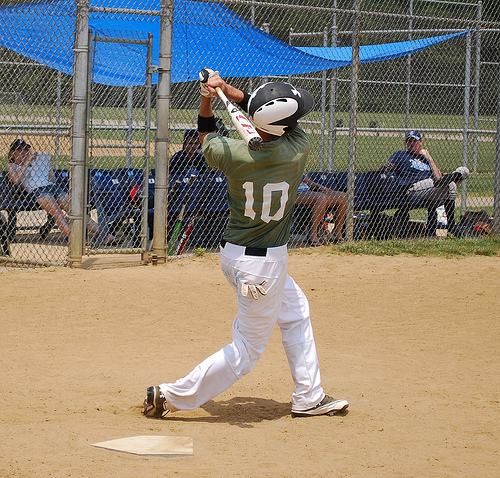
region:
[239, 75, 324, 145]
white and black helmet on baseball player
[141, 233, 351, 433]
white pants on baseball player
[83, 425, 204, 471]
white home plate next to baseball player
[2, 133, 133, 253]
person behind fence watching baseball player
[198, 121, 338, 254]
baseball player with green shirt and white numbers on it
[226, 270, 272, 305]
white glove in back pocket of baseball player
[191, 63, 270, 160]
baseball bat in the hands of baseball player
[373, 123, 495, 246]
man in blue uniform behind fence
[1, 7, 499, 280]
metal fence behind baseball player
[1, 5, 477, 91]
blue tarp behind fence and baseball player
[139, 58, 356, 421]
baseball batter swinging bat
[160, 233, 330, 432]
men's white sports pants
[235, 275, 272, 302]
white glove hanging from pocket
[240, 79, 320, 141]
black and white baseball helmet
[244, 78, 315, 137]
white and black safety helmet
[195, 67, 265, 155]
baseball bat in batter's hands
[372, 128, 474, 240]
person sitting on bench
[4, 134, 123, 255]
woman in denim shorts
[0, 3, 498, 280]
safety fence behind batter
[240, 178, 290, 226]
number 10 on green jersey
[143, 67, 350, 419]
Man playing baseball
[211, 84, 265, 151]
Bat in the man's hands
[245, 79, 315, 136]
Helmet on the man's head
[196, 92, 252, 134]
Bands on the man's arms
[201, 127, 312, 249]
Shirt on the man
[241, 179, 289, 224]
Number on the man's shirt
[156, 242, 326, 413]
White pants on the man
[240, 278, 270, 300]
Glove on the man's pants pocket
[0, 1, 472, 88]
A piece of blue cloth in the air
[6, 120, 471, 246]
People sitting under the cloth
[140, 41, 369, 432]
The man is on the field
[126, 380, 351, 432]
The feet of the man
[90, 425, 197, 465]
The plate on the ground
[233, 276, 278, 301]
The man has a glove in his pocket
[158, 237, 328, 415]
The man has on white pants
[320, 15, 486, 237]
The gate is made of metal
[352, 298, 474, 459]
The dirt is the color brown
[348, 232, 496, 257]
The grass is short and green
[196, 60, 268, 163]
The man is holding a bat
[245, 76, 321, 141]
The man has on a helmet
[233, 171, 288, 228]
The number ten written in white on a green background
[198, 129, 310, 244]
A green baseball uniform with white writing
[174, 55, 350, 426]
A young boy playing baseball and swinging his bat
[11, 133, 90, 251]
A woman behind a fence reclining and wearing denim shorts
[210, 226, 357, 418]
Pair of khakis colored white being worn over black and white shoes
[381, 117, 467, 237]
Man sitting in the stands wearing a blue baseball cap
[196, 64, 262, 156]
Black and white baseball bat with red coloring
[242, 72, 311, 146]
Black and white baseball helmet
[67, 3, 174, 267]
Gray metal gate of a fence at a baseball field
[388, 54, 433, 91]
green leaves on the tree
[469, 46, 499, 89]
green leaves on the tree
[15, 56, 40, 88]
green leaves on the tree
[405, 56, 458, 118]
green leaves on the tree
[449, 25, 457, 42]
green leaves on the tree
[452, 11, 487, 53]
green leaves on the tree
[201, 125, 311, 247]
Green shirt on baseball player.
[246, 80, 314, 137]
Batting helmet on baseball player.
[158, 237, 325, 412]
White pants on baseball player.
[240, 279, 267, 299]
Glove hanging from pocket of baseball player.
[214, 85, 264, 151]
Baseball bat held by baseball player.